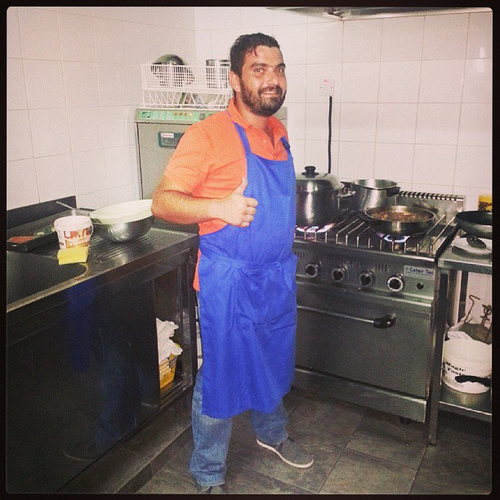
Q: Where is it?
A: This is at the kitchen.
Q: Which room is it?
A: It is a kitchen.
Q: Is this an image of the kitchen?
A: Yes, it is showing the kitchen.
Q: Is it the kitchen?
A: Yes, it is the kitchen.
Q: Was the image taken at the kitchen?
A: Yes, it was taken in the kitchen.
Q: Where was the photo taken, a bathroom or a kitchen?
A: It was taken at a kitchen.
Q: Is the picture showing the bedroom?
A: No, the picture is showing the kitchen.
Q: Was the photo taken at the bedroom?
A: No, the picture was taken in the kitchen.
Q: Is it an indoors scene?
A: Yes, it is indoors.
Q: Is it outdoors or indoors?
A: It is indoors.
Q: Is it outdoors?
A: No, it is indoors.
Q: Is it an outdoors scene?
A: No, it is indoors.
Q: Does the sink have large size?
A: Yes, the sink is large.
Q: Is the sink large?
A: Yes, the sink is large.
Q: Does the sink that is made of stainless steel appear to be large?
A: Yes, the sink is large.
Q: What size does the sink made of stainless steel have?
A: The sink has large size.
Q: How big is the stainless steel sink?
A: The sink is large.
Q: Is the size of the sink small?
A: No, the sink is large.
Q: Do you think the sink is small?
A: No, the sink is large.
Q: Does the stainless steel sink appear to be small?
A: No, the sink is large.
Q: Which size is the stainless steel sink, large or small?
A: The sink is large.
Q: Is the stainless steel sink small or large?
A: The sink is large.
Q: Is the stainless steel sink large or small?
A: The sink is large.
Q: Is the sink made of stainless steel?
A: Yes, the sink is made of stainless steel.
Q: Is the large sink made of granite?
A: No, the sink is made of stainless steel.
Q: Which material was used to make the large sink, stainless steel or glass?
A: The sink is made of stainless steel.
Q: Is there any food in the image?
A: Yes, there is food.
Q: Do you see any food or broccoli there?
A: Yes, there is food.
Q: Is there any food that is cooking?
A: Yes, there is food that is cooking.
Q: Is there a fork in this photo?
A: No, there are no forks.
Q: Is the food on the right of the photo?
A: Yes, the food is on the right of the image.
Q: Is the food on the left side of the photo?
A: No, the food is on the right of the image.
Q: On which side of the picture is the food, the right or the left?
A: The food is on the right of the image.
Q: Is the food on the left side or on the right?
A: The food is on the right of the image.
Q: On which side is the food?
A: The food is on the right of the image.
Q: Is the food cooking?
A: Yes, the food is cooking.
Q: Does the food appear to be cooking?
A: Yes, the food is cooking.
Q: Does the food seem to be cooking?
A: Yes, the food is cooking.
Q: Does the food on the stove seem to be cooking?
A: Yes, the food is cooking.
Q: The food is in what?
A: The food is in the pan.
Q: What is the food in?
A: The food is in the pan.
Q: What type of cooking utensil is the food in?
A: The food is in the pan.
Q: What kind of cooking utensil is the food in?
A: The food is in the pan.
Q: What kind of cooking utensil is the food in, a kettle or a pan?
A: The food is in a pan.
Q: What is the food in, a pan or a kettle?
A: The food is in a pan.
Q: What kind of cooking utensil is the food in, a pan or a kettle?
A: The food is in a pan.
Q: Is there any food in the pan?
A: Yes, there is food in the pan.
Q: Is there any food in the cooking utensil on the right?
A: Yes, there is food in the pan.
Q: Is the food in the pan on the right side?
A: Yes, the food is in the pan.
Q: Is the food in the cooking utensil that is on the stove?
A: Yes, the food is in the pan.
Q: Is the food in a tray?
A: No, the food is in the pan.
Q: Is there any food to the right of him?
A: Yes, there is food to the right of the man.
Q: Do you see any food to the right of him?
A: Yes, there is food to the right of the man.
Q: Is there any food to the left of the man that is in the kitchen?
A: No, the food is to the right of the man.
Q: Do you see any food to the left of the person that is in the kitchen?
A: No, the food is to the right of the man.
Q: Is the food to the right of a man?
A: Yes, the food is to the right of a man.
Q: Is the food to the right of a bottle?
A: No, the food is to the right of a man.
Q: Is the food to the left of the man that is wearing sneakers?
A: No, the food is to the right of the man.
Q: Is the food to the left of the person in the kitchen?
A: No, the food is to the right of the man.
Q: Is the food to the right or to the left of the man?
A: The food is to the right of the man.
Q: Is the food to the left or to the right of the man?
A: The food is to the right of the man.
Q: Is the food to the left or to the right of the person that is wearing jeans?
A: The food is to the right of the man.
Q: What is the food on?
A: The food is on the stove.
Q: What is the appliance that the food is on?
A: The appliance is a stove.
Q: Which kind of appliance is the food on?
A: The food is on the stove.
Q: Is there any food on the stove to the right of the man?
A: Yes, there is food on the stove.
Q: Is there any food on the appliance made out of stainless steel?
A: Yes, there is food on the stove.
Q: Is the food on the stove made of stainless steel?
A: Yes, the food is on the stove.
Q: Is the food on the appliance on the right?
A: Yes, the food is on the stove.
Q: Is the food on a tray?
A: No, the food is on the stove.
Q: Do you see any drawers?
A: No, there are no drawers.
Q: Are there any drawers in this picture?
A: No, there are no drawers.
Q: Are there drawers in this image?
A: No, there are no drawers.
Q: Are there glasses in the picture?
A: No, there are no glasses.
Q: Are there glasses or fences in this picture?
A: No, there are no glasses or fences.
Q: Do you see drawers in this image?
A: No, there are no drawers.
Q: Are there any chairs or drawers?
A: No, there are no drawers or chairs.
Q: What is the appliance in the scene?
A: The appliance is a stove.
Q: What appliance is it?
A: The appliance is a stove.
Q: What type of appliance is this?
A: This is a stove.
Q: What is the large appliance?
A: The appliance is a stove.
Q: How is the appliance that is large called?
A: The appliance is a stove.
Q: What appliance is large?
A: The appliance is a stove.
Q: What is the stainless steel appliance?
A: The appliance is a stove.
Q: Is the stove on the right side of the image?
A: Yes, the stove is on the right of the image.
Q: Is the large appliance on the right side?
A: Yes, the stove is on the right of the image.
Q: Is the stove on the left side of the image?
A: No, the stove is on the right of the image.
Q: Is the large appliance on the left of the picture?
A: No, the stove is on the right of the image.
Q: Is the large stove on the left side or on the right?
A: The stove is on the right of the image.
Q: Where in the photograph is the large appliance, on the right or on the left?
A: The stove is on the right of the image.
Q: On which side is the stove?
A: The stove is on the right of the image.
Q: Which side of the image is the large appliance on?
A: The stove is on the right of the image.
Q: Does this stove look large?
A: Yes, the stove is large.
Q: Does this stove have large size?
A: Yes, the stove is large.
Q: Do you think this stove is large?
A: Yes, the stove is large.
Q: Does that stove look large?
A: Yes, the stove is large.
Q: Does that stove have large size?
A: Yes, the stove is large.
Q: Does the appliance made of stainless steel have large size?
A: Yes, the stove is large.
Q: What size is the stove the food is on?
A: The stove is large.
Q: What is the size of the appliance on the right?
A: The stove is large.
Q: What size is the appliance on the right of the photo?
A: The stove is large.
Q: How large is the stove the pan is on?
A: The stove is large.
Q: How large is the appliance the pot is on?
A: The stove is large.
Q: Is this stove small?
A: No, the stove is large.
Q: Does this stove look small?
A: No, the stove is large.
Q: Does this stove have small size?
A: No, the stove is large.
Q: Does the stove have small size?
A: No, the stove is large.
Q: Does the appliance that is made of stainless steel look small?
A: No, the stove is large.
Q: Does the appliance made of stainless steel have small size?
A: No, the stove is large.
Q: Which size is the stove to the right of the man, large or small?
A: The stove is large.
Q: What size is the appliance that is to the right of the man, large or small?
A: The stove is large.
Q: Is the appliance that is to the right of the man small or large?
A: The stove is large.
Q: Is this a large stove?
A: Yes, this is a large stove.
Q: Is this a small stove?
A: No, this is a large stove.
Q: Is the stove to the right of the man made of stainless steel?
A: Yes, the stove is made of stainless steel.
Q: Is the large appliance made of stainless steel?
A: Yes, the stove is made of stainless steel.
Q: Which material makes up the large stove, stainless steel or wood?
A: The stove is made of stainless steel.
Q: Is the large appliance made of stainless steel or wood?
A: The stove is made of stainless steel.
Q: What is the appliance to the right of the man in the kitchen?
A: The appliance is a stove.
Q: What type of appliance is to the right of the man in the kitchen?
A: The appliance is a stove.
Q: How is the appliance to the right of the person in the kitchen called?
A: The appliance is a stove.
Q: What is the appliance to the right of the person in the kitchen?
A: The appliance is a stove.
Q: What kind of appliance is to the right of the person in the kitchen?
A: The appliance is a stove.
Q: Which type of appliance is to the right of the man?
A: The appliance is a stove.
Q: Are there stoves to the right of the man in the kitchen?
A: Yes, there is a stove to the right of the man.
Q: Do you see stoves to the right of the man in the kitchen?
A: Yes, there is a stove to the right of the man.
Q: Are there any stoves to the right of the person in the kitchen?
A: Yes, there is a stove to the right of the man.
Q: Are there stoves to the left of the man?
A: No, the stove is to the right of the man.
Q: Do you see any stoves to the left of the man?
A: No, the stove is to the right of the man.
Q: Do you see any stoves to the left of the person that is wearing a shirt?
A: No, the stove is to the right of the man.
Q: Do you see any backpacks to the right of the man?
A: No, there is a stove to the right of the man.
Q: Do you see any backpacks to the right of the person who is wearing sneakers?
A: No, there is a stove to the right of the man.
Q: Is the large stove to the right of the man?
A: Yes, the stove is to the right of the man.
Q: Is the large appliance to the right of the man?
A: Yes, the stove is to the right of the man.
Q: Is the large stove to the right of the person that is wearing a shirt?
A: Yes, the stove is to the right of the man.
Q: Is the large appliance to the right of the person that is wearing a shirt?
A: Yes, the stove is to the right of the man.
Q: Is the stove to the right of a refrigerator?
A: No, the stove is to the right of the man.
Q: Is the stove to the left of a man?
A: No, the stove is to the right of a man.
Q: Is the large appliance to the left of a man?
A: No, the stove is to the right of a man.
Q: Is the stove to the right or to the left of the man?
A: The stove is to the right of the man.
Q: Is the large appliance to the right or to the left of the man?
A: The stove is to the right of the man.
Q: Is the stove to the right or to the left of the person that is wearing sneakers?
A: The stove is to the right of the man.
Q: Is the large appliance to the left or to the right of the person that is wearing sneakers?
A: The stove is to the right of the man.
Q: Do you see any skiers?
A: No, there are no skiers.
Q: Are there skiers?
A: No, there are no skiers.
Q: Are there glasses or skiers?
A: No, there are no skiers or glasses.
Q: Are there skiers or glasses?
A: No, there are no skiers or glasses.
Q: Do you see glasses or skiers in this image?
A: No, there are no skiers or glasses.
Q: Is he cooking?
A: Yes, the man is cooking.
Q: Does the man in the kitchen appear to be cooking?
A: Yes, the man is cooking.